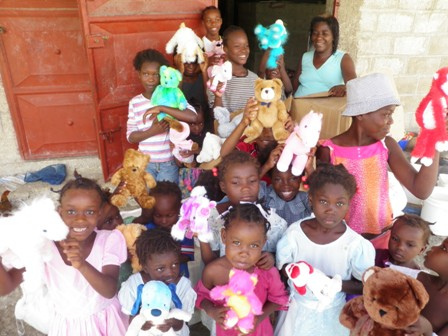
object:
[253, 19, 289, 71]
stuffed animal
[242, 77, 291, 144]
stuffed animal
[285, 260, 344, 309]
dog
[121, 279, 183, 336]
dog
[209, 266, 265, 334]
bear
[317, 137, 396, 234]
shirt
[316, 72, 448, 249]
girl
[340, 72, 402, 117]
hat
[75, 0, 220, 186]
door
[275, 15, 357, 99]
woman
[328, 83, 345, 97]
hand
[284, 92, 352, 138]
box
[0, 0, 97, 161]
door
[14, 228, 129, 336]
dress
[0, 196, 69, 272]
unicorn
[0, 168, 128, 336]
child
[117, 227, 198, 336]
child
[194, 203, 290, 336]
child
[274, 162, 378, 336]
child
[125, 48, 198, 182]
child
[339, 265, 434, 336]
stuffed animal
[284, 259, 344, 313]
stuffed animal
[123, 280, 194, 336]
stuffed animal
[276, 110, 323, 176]
stuffed animal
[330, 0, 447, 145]
wall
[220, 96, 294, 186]
kid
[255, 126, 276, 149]
head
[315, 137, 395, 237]
dress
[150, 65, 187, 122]
animal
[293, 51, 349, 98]
tank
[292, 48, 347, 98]
tank top